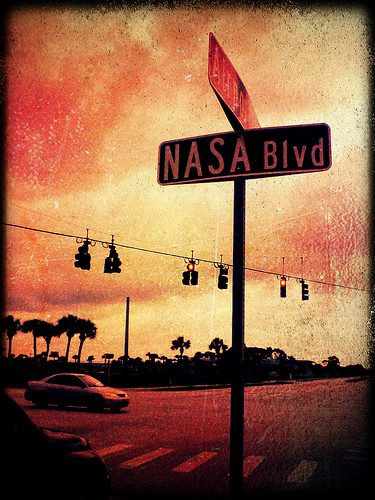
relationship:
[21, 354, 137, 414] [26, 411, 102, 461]
car next to camera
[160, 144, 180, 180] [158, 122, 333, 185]
letters on sign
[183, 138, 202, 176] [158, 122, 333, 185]
letters on sign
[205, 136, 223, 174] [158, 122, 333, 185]
letters on sign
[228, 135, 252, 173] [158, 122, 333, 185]
letters on sign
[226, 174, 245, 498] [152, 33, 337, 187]
pole under sign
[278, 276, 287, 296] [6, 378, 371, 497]
light above ground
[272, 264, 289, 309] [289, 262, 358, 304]
light on rope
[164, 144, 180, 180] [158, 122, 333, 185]
letters on sign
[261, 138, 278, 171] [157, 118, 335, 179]
letter b of a sign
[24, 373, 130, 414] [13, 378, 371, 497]
car driving down road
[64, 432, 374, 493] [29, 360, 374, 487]
crosswalk on a city street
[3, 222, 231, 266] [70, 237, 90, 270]
line on line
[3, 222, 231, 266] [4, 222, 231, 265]
line on line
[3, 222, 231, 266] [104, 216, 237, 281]
line on line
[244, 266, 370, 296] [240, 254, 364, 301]
line on line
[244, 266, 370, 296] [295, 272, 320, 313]
line on line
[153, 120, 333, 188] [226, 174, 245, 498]
street sign on pole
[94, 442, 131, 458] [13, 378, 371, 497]
line on road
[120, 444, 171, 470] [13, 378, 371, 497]
line on road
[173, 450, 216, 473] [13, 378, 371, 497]
line on road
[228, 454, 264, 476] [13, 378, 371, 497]
line on road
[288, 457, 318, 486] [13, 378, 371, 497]
line on road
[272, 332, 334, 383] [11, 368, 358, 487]
buildings next to road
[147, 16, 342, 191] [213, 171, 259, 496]
signs on pole